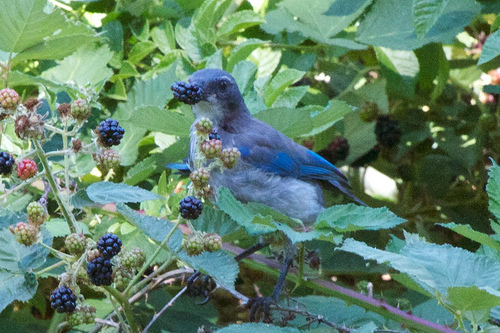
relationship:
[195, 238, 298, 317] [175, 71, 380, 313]
legs of bird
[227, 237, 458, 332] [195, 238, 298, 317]
twig under legs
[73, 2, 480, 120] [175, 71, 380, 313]
leaves around bird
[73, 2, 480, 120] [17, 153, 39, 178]
leaves around fruit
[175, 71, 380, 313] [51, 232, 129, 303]
bird by fruit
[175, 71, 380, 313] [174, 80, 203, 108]
bird eating fruit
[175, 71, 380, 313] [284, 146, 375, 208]
bird has wing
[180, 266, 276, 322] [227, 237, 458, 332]
claws on twig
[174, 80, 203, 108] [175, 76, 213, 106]
fruit in beak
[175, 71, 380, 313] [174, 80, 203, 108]
bird with fruit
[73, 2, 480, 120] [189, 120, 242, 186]
leaves surround fruit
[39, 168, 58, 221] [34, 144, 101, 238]
thorns on branch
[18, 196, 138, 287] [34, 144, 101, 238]
berries on branch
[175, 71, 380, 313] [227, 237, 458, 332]
bird on twig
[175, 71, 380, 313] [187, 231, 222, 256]
bird eating berries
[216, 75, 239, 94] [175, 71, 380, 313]
eye on bird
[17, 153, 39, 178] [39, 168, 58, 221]
fruit has thorns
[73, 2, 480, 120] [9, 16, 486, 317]
leaves on bush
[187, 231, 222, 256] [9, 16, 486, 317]
berries on bush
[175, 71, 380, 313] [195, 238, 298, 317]
bird has legs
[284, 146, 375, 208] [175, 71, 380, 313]
wing on bird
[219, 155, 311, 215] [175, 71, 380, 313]
chest of bird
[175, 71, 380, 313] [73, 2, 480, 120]
bird around leaves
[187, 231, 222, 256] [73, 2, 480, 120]
berries in leaves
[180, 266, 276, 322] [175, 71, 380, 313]
claws on bird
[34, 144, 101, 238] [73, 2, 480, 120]
branch has leaves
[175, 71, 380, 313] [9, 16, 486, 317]
bird in bush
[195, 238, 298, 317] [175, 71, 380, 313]
legs on bird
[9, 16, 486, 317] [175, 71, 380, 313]
bush around bird